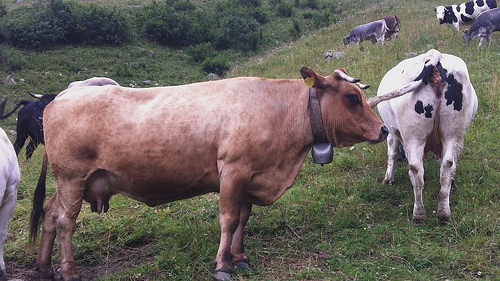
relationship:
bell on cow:
[310, 142, 335, 166] [33, 68, 396, 277]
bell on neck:
[310, 142, 335, 166] [278, 72, 323, 158]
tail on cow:
[356, 38, 442, 107] [360, 42, 484, 227]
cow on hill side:
[467, 14, 484, 44] [249, 22, 254, 29]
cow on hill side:
[433, 4, 484, 28] [249, 22, 254, 29]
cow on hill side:
[342, 18, 394, 52] [249, 22, 254, 29]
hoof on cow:
[412, 206, 425, 224] [366, 47, 478, 224]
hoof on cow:
[434, 208, 450, 220] [366, 47, 478, 224]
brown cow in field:
[30, 62, 388, 281] [13, 10, 484, 260]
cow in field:
[339, 20, 389, 56] [240, 28, 282, 61]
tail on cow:
[0, 94, 27, 122] [0, 90, 52, 165]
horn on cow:
[338, 68, 374, 95] [362, 47, 494, 233]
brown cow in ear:
[30, 62, 388, 281] [300, 60, 327, 90]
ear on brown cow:
[300, 60, 327, 90] [30, 62, 388, 281]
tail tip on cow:
[21, 145, 52, 246] [33, 68, 396, 277]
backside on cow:
[363, 50, 484, 222] [382, 55, 469, 224]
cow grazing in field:
[339, 20, 389, 56] [13, 10, 484, 260]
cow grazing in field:
[372, 15, 402, 41] [13, 10, 484, 260]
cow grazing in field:
[462, 7, 500, 44] [13, 10, 484, 260]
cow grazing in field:
[433, 0, 497, 36] [13, 10, 484, 260]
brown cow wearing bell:
[30, 62, 388, 279] [311, 142, 333, 163]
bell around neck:
[306, 142, 338, 162] [281, 67, 331, 144]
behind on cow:
[400, 51, 474, 153] [366, 47, 478, 224]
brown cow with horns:
[30, 62, 388, 281] [328, 52, 383, 95]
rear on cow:
[364, 49, 476, 225] [396, 47, 471, 201]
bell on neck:
[310, 142, 335, 166] [288, 65, 344, 177]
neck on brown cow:
[288, 65, 344, 177] [30, 62, 388, 281]